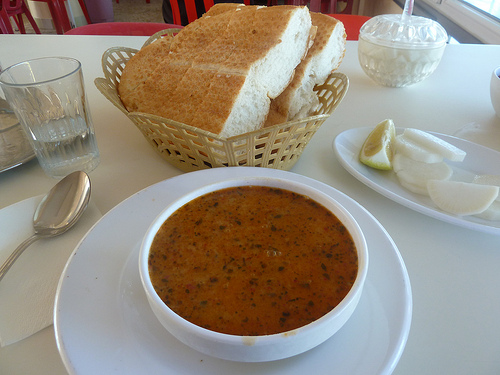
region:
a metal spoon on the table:
[0, 164, 93, 286]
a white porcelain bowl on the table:
[135, 175, 370, 364]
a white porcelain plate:
[45, 160, 422, 373]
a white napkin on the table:
[0, 181, 115, 353]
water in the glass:
[25, 113, 97, 183]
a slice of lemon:
[356, 106, 401, 173]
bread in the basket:
[113, 0, 353, 160]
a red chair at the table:
[57, 12, 202, 38]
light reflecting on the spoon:
[76, 170, 92, 200]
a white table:
[0, 30, 499, 373]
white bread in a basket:
[95, 5, 350, 175]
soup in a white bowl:
[137, 172, 369, 361]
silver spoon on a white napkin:
[1, 169, 101, 341]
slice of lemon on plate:
[358, 118, 399, 171]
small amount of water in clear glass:
[0, 55, 103, 182]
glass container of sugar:
[358, 0, 449, 89]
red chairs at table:
[0, 0, 372, 42]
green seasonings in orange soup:
[144, 185, 358, 335]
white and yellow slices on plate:
[333, 116, 499, 233]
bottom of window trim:
[420, 0, 499, 44]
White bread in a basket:
[128, 2, 318, 154]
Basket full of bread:
[96, 12, 349, 174]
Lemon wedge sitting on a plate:
[356, 109, 398, 176]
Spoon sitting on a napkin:
[0, 164, 95, 291]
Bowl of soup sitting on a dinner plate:
[140, 173, 371, 364]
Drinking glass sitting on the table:
[0, 51, 98, 181]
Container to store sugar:
[355, 3, 449, 96]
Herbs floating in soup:
[206, 213, 300, 305]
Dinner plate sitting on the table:
[50, 163, 420, 374]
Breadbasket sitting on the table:
[94, 1, 356, 181]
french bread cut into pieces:
[178, 14, 298, 111]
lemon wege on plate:
[359, 113, 404, 176]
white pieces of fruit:
[408, 129, 478, 208]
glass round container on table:
[366, 13, 449, 85]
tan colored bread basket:
[128, 86, 355, 156]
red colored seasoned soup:
[214, 200, 300, 291]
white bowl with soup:
[154, 229, 402, 359]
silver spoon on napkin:
[4, 196, 92, 236]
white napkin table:
[20, 248, 58, 349]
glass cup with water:
[0, 49, 120, 168]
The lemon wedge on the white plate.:
[371, 125, 398, 176]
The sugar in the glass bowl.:
[357, 42, 442, 90]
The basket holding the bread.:
[107, 42, 353, 159]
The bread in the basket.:
[136, 7, 341, 111]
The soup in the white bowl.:
[175, 190, 329, 312]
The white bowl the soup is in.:
[137, 176, 363, 371]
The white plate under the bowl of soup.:
[76, 162, 415, 372]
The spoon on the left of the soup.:
[5, 159, 100, 309]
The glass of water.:
[3, 60, 110, 187]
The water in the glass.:
[33, 120, 105, 165]